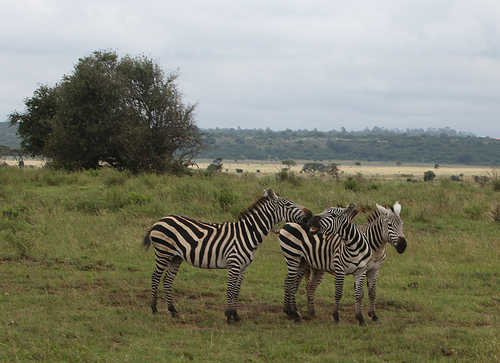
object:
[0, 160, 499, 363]
grass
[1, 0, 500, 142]
overcast sky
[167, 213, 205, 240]
stripes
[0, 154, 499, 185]
dry grass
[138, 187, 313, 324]
zebra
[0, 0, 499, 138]
clouds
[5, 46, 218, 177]
tree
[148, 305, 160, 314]
hoof(foot)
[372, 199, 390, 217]
ear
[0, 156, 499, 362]
ground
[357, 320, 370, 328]
foot